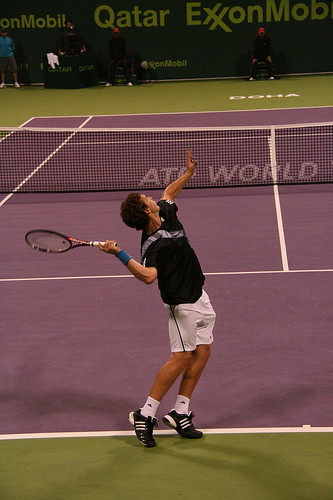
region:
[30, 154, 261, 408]
a tennis player is about to serve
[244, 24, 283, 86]
a tennis court judge is watching the ball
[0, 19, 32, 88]
a person is wearing a blue T-shirt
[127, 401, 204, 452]
a tennis player is wearing Adidas sneakers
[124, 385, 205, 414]
a tennis player is wearing Adidas socks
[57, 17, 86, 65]
a camera man is standing and filming the game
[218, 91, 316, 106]
a writing indicating that this is taking place in DOHA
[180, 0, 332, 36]
a sponsor sign indicating Exxon Mobile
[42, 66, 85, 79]
a sign indicating that this is taking place in QATAR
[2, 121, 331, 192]
a tennis net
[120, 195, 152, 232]
man has brown hair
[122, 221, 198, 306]
man has black shirt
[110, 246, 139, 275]
man has blue wrist band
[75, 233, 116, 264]
white grip on tennis racket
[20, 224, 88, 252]
black and red racket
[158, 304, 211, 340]
man has white pants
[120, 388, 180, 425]
man wears white socks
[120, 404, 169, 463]
black and white shoes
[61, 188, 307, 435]
tennis court is grey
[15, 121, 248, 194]
black and white net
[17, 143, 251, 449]
Man playing tennis on purple and green tennis court.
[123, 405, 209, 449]
Man wearing black and white tennis shoes.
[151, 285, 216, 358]
Man dressed in white shorts with black stripe down side.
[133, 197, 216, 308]
Man dressed in black shirt with gray accent.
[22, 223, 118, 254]
Man holding tennis racket in hand.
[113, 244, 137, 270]
Man wearing blue band around wrist.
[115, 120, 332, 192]
Tennis net stretched across court.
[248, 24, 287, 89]
Man sitting in background at end of tennis court.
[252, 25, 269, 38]
Man at end of tennis court wearing orange cap.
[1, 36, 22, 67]
Man standing at end of tennis court wearing blue shirt.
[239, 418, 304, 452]
white line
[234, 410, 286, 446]
white line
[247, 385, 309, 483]
white line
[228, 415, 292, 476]
white line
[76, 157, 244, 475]
professional tennis player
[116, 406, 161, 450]
Adidas tennis shoes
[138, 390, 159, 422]
white Adidas athletic socks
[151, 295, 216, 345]
white and black tennis shorts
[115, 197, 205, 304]
black, white and gray tennis shirt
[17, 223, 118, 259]
red and black tennis racket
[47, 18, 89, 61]
man operating a television camera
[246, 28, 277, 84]
tennis ball boy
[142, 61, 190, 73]
advertisement for exxon mobile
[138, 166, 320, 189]
advertisement for ato world